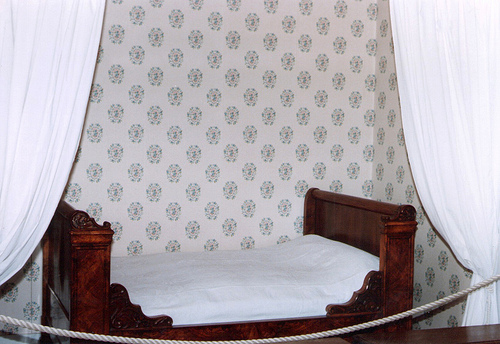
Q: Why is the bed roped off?
A: It is in a museum.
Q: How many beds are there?
A: One.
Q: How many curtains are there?
A: Two.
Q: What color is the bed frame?
A: Brown.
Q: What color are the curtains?
A: White.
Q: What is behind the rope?
A: A bed.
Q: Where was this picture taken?
A: A museum.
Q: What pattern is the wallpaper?
A: Flowers.